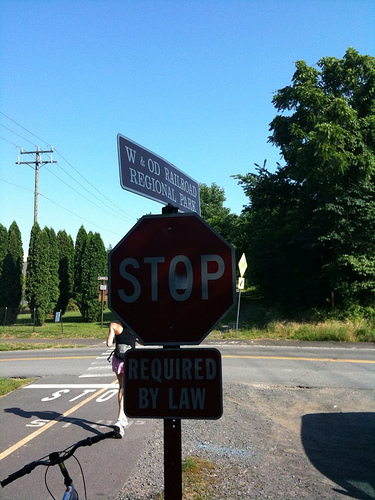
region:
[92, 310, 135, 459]
A girl jogging in the street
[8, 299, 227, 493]
A bike at a stop sign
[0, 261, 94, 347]
Tall green trees on a corner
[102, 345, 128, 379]
The girl is wearing pink shorts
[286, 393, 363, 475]
A shadow on the ground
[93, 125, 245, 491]
A pole holding three signs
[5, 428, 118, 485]
Handlebars on a bicycle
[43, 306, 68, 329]
A sign in a yard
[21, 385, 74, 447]
Yellow stripe painted on the asphalt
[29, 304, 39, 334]
A green metal post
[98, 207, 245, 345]
red and white stop sign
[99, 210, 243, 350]
red octagonal stop sign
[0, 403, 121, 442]
shadow of person on ground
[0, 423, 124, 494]
bike handlebars tilted sideways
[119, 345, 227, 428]
rectangular red sign with white lettering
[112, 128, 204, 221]
black and white rectangular sign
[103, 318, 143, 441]
jogger in pink shorts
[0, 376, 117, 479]
yellow roadway center line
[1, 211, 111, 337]
grove of poplar trees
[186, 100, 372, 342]
leafy green trees on right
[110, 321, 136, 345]
the woman is wearing a tank top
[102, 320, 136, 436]
the woman is jogging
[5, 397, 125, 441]
a shadow is on the road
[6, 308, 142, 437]
the woman is casting a shadow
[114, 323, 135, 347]
the tank top is black in color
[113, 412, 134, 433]
the woman is wearing athletic shoes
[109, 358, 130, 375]
the woman is wearing shorts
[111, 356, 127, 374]
the shorts are pink in color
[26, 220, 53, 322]
the tree is in the background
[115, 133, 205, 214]
a green sign that states W & OD Railroad Regional Park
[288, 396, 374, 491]
the shadow of a car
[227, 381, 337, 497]
washed out gravel and dirt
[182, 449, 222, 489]
a small patch of grass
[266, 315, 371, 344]
tall unkeeped weeds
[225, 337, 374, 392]
a two land road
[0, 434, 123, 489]
black bike handles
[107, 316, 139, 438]
the back of a woman running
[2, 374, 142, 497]
a paved bike trial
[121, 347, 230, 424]
Required by Law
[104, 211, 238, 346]
octagon red stop sign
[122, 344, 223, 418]
rectangular red sign under stop sign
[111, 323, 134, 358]
woman wearing black tank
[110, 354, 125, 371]
woman wearing pink shorts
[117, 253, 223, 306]
white writing on stop sign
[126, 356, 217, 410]
white writing on rectangular sign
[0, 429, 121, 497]
blue bike near sign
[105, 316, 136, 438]
woman jogging down street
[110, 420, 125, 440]
woman wearing white shoe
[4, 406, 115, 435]
shadow of woman on street